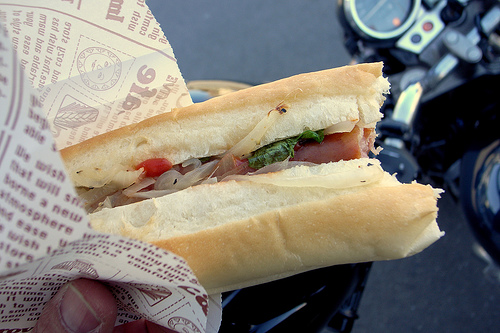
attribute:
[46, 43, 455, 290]
sandwich — hoagie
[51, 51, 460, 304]
bread — plain, toasted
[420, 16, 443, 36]
button — red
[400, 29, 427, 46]
button — blue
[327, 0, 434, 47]
meter — round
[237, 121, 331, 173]
lettuce — green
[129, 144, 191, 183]
tomato — small, red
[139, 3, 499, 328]
cement — gray